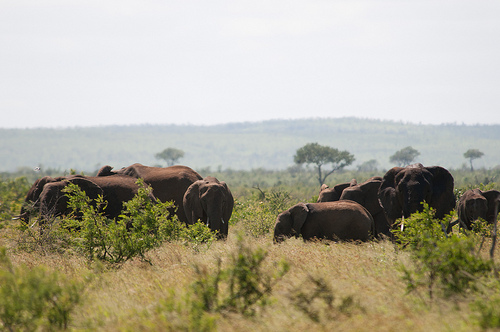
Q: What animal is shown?
A: Elephants.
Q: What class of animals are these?
A: Mammals.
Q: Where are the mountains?
A: Background.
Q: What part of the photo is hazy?
A: Sky.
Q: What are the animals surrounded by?
A: Tall grass.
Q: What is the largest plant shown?
A: Trees.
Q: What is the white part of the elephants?
A: Tusks.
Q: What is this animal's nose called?
A: Trunk.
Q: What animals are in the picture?
A: Elephants.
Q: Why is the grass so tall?
A: This is a forest.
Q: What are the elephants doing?
A: Walking in the grass.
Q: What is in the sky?
A: Clouds.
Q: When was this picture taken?
A: On a cloudy day.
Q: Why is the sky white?
A: It's overcast.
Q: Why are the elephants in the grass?
A: They are grazing.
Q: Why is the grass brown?
A: It's dry.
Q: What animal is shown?
A: Elephant.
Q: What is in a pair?
A: Elephants.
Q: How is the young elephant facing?
A: Left.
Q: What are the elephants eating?
A: Grass.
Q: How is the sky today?
A: Hazy.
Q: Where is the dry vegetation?
A: On the flat land.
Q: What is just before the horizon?
A: Mountains.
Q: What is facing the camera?
A: Elephants.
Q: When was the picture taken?
A: During daylight hours.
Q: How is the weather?
A: Clear and sunny.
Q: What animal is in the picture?
A: Elephants.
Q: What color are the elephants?
A: Gray.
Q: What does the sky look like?
A: Hazy.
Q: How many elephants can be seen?
A: 9.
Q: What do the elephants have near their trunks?
A: Tusks.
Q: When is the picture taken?
A: Daytime.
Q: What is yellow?
A: The long grass.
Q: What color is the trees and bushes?
A: Green.